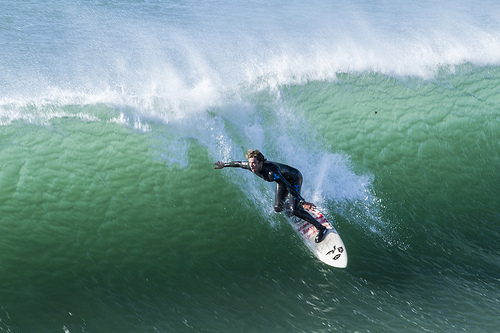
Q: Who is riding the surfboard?
A: A man.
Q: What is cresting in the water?
A: Wave.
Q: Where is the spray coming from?
A: The wave.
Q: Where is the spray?
A: Behind the surfboard.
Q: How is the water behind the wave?
A: Calm.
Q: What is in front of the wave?
A: Foam.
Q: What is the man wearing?
A: Wetsuit.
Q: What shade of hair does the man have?
A: Blonde.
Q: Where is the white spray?
A: Behind surfer.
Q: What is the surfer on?
A: White surfboard.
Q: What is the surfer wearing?
A: Black wetsuit.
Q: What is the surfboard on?
A: Blue wave.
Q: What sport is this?
A: Surfing.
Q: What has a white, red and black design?
A: Surfboard.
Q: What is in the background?
A: Ocean wave.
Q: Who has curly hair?
A: Surfer.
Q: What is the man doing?
A: Surfing.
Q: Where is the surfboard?
A: Under the man.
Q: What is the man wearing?
A: A wet suit.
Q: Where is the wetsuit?
A: On the man.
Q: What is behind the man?
A: A wave.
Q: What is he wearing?
A: A wetsuit.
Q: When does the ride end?
A: When the wave goes ashore.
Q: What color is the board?
A: Mostly white with graphics.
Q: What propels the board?
A: The surge of the wave.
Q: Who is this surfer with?
A: He is alone.